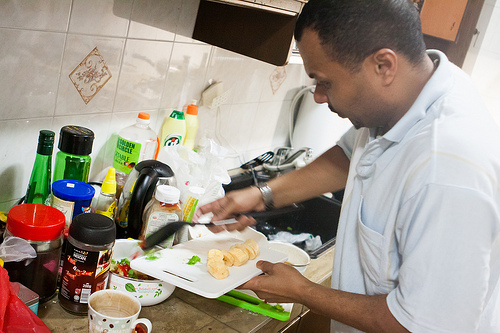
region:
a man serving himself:
[112, 23, 495, 329]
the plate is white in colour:
[131, 220, 306, 312]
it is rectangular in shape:
[137, 212, 302, 324]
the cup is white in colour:
[43, 283, 161, 330]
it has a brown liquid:
[85, 275, 160, 332]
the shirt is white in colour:
[352, 168, 496, 330]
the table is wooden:
[161, 297, 225, 332]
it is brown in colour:
[167, 301, 226, 327]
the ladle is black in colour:
[116, 215, 249, 250]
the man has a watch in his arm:
[232, 173, 282, 219]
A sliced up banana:
[201, 230, 262, 276]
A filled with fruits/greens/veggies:
[90, 221, 180, 308]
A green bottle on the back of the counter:
[15, 120, 60, 206]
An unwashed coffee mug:
[72, 275, 152, 330]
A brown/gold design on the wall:
[56, 35, 121, 110]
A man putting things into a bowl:
[130, 0, 495, 330]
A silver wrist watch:
[247, 170, 277, 215]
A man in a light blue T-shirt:
[135, 0, 495, 330]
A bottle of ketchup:
[131, 180, 186, 245]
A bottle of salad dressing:
[87, 161, 123, 222]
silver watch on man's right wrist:
[248, 176, 288, 211]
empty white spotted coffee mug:
[77, 287, 162, 331]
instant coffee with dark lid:
[58, 206, 121, 318]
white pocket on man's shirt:
[356, 198, 396, 277]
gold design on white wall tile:
[63, 32, 138, 124]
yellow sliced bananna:
[202, 243, 274, 274]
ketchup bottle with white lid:
[144, 178, 179, 248]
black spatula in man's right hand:
[133, 199, 309, 255]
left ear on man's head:
[354, 42, 424, 94]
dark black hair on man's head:
[324, 5, 436, 49]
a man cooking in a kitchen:
[240, 0, 498, 328]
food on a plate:
[205, 237, 262, 271]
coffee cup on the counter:
[75, 288, 143, 332]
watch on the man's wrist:
[248, 178, 285, 216]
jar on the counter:
[61, 210, 116, 311]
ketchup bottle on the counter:
[146, 183, 188, 243]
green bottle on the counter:
[30, 123, 53, 198]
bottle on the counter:
[119, 111, 162, 159]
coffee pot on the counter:
[130, 155, 170, 195]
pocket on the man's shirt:
[346, 200, 393, 282]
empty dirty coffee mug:
[84, 288, 151, 331]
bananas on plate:
[201, 237, 263, 279]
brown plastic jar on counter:
[58, 209, 115, 319]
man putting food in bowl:
[129, 2, 497, 330]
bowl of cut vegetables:
[96, 232, 177, 309]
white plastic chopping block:
[122, 231, 291, 301]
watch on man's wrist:
[257, 178, 276, 210]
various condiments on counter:
[6, 102, 201, 317]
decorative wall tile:
[53, 29, 126, 116]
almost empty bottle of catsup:
[134, 181, 184, 255]